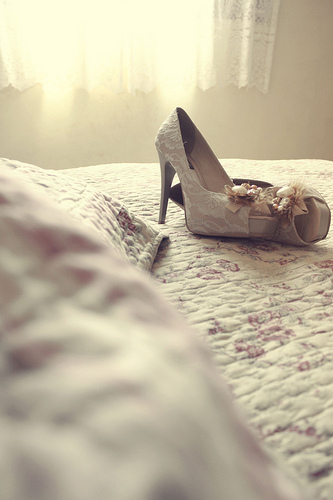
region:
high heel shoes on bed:
[154, 105, 330, 245]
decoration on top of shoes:
[227, 181, 296, 214]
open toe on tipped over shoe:
[290, 195, 330, 244]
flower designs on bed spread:
[242, 290, 295, 353]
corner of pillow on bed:
[53, 172, 161, 263]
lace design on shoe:
[191, 194, 229, 224]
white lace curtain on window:
[170, 10, 285, 93]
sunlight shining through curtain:
[60, 2, 159, 84]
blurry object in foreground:
[57, 263, 171, 405]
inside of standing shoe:
[190, 147, 210, 174]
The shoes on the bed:
[151, 106, 331, 249]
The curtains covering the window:
[0, 0, 280, 97]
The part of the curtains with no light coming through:
[217, 0, 285, 97]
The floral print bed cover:
[0, 154, 329, 497]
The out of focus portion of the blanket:
[0, 165, 315, 498]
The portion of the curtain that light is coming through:
[5, 0, 213, 91]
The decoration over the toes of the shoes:
[228, 179, 298, 209]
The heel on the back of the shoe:
[152, 155, 169, 218]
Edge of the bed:
[39, 153, 330, 168]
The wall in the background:
[0, 1, 330, 168]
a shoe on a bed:
[153, 106, 276, 240]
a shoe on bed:
[169, 176, 330, 245]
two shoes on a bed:
[154, 104, 331, 244]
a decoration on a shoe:
[222, 179, 257, 200]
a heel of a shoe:
[147, 145, 174, 223]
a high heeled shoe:
[150, 108, 275, 242]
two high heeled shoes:
[153, 106, 330, 242]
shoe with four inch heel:
[154, 103, 274, 240]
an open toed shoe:
[152, 105, 275, 241]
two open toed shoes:
[147, 102, 331, 246]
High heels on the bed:
[126, 93, 327, 223]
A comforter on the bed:
[254, 349, 310, 427]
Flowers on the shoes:
[229, 164, 330, 234]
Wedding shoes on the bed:
[153, 123, 316, 430]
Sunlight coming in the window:
[79, 29, 196, 68]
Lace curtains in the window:
[147, 8, 299, 96]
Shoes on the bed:
[61, 141, 323, 276]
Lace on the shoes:
[151, 121, 278, 211]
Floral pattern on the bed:
[241, 288, 321, 462]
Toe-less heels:
[228, 161, 302, 223]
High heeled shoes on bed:
[136, 112, 329, 241]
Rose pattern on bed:
[204, 299, 300, 344]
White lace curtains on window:
[2, 5, 280, 95]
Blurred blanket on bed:
[33, 342, 230, 460]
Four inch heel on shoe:
[157, 157, 171, 220]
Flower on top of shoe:
[226, 180, 262, 214]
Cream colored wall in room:
[257, 106, 328, 153]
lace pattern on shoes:
[148, 110, 190, 156]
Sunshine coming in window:
[50, 17, 190, 62]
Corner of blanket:
[108, 220, 171, 261]